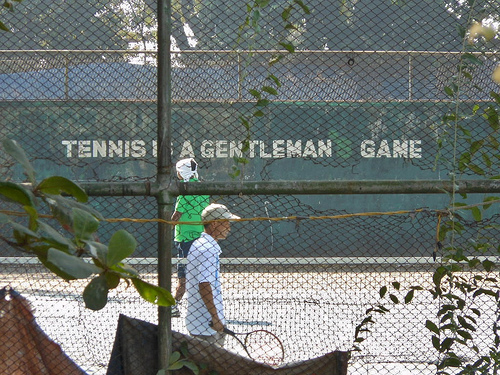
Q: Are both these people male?
A: No, they are both male and female.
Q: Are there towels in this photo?
A: Yes, there is a towel.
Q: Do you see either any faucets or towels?
A: Yes, there is a towel.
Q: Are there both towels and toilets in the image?
A: No, there is a towel but no toilets.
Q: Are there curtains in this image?
A: No, there are no curtains.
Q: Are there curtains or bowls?
A: No, there are no curtains or bowls.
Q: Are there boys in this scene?
A: No, there are no boys.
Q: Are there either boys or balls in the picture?
A: No, there are no boys or balls.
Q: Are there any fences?
A: Yes, there is a fence.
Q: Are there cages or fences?
A: Yes, there is a fence.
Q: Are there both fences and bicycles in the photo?
A: No, there is a fence but no bicycles.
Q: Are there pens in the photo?
A: No, there are no pens.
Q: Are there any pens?
A: No, there are no pens.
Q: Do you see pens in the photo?
A: No, there are no pens.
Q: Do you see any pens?
A: No, there are no pens.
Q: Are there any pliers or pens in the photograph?
A: No, there are no pens or pliers.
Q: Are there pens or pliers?
A: No, there are no pens or pliers.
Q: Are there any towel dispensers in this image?
A: No, there are no towel dispensers.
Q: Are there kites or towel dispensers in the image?
A: No, there are no towel dispensers or kites.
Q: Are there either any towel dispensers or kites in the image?
A: No, there are no towel dispensers or kites.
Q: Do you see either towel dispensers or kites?
A: No, there are no towel dispensers or kites.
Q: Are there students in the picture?
A: No, there are no students.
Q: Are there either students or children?
A: No, there are no students or children.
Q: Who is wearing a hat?
A: The man is wearing a hat.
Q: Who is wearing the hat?
A: The man is wearing a hat.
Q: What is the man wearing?
A: The man is wearing a hat.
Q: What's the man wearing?
A: The man is wearing a hat.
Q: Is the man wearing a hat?
A: Yes, the man is wearing a hat.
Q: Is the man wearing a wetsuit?
A: No, the man is wearing a hat.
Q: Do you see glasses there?
A: No, there are no glasses.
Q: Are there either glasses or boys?
A: No, there are no glasses or boys.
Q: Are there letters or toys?
A: Yes, there are letters.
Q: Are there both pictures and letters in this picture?
A: No, there are letters but no pictures.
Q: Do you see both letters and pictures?
A: No, there are letters but no pictures.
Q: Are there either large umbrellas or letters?
A: Yes, there are large letters.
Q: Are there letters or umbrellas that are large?
A: Yes, the letters are large.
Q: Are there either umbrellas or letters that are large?
A: Yes, the letters are large.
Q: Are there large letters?
A: Yes, there are large letters.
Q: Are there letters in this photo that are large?
A: Yes, there are letters that are large.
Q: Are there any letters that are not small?
A: Yes, there are large letters.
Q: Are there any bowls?
A: No, there are no bowls.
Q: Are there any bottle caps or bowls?
A: No, there are no bowls or bottle caps.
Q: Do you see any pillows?
A: No, there are no pillows.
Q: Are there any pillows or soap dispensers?
A: No, there are no pillows or soap dispensers.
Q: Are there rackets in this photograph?
A: Yes, there is a racket.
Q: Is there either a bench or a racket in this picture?
A: Yes, there is a racket.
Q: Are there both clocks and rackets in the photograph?
A: No, there is a racket but no clocks.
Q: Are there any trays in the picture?
A: No, there are no trays.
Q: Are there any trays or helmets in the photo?
A: No, there are no trays or helmets.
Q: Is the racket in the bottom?
A: Yes, the racket is in the bottom of the image.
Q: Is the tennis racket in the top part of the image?
A: No, the tennis racket is in the bottom of the image.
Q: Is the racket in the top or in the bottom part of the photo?
A: The racket is in the bottom of the image.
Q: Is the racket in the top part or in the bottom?
A: The racket is in the bottom of the image.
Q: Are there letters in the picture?
A: Yes, there are letters.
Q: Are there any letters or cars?
A: Yes, there are letters.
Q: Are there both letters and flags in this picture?
A: No, there are letters but no flags.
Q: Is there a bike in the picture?
A: No, there are no bikes.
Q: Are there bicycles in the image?
A: No, there are no bicycles.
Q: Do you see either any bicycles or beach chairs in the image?
A: No, there are no bicycles or beach chairs.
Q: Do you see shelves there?
A: No, there are no shelves.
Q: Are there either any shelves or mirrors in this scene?
A: No, there are no shelves or mirrors.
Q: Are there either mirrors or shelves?
A: No, there are no shelves or mirrors.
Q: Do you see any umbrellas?
A: No, there are no umbrellas.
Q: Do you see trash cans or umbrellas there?
A: No, there are no umbrellas or trash cans.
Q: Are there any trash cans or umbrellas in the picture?
A: No, there are no umbrellas or trash cans.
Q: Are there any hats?
A: Yes, there is a hat.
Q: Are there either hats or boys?
A: Yes, there is a hat.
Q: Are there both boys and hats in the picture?
A: No, there is a hat but no boys.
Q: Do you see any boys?
A: No, there are no boys.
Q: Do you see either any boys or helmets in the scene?
A: No, there are no boys or helmets.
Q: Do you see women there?
A: Yes, there is a woman.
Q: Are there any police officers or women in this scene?
A: Yes, there is a woman.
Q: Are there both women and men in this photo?
A: Yes, there are both a woman and a man.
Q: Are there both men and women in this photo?
A: Yes, there are both a woman and a man.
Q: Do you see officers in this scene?
A: No, there are no officers.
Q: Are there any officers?
A: No, there are no officers.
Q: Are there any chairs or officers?
A: No, there are no officers or chairs.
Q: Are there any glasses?
A: No, there are no glasses.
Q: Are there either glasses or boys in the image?
A: No, there are no glasses or boys.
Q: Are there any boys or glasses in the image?
A: No, there are no glasses or boys.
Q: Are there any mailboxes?
A: No, there are no mailboxes.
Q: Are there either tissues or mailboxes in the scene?
A: No, there are no mailboxes or tissues.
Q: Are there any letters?
A: Yes, there are letters.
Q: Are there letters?
A: Yes, there are letters.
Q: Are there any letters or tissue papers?
A: Yes, there are letters.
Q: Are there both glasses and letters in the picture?
A: No, there are letters but no glasses.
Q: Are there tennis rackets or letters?
A: Yes, there are tennis letters.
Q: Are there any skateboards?
A: No, there are no skateboards.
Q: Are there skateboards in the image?
A: No, there are no skateboards.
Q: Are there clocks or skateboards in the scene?
A: No, there are no skateboards or clocks.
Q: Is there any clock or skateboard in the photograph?
A: No, there are no skateboards or clocks.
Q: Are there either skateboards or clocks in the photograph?
A: No, there are no skateboards or clocks.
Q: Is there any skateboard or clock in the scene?
A: No, there are no skateboards or clocks.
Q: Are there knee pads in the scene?
A: No, there are no knee pads.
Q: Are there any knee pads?
A: No, there are no knee pads.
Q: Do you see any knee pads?
A: No, there are no knee pads.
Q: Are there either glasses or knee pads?
A: No, there are no knee pads or glasses.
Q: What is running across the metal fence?
A: The wire is running across the fence.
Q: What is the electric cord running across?
A: The cord is running across the fence.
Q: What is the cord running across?
A: The cord is running across the fence.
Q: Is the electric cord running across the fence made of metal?
A: Yes, the cord is running across the fence.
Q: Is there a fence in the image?
A: Yes, there is a fence.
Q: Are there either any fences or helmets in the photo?
A: Yes, there is a fence.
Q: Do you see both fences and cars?
A: No, there is a fence but no cars.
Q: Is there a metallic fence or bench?
A: Yes, there is a metal fence.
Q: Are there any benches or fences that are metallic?
A: Yes, the fence is metallic.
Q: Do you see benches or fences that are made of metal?
A: Yes, the fence is made of metal.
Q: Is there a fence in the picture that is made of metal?
A: Yes, there is a fence that is made of metal.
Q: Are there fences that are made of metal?
A: Yes, there is a fence that is made of metal.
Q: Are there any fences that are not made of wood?
A: Yes, there is a fence that is made of metal.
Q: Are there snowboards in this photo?
A: No, there are no snowboards.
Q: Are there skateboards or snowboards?
A: No, there are no snowboards or skateboards.